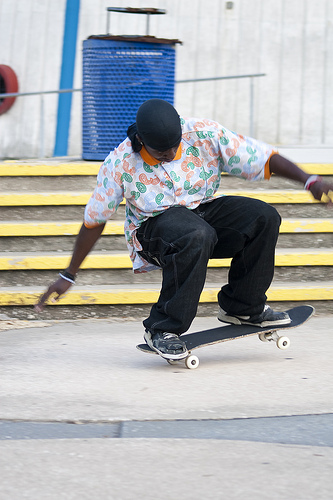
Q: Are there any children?
A: No, there are no children.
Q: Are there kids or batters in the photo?
A: No, there are no kids or batters.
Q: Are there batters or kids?
A: No, there are no kids or batters.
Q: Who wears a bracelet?
A: The guy wears a bracelet.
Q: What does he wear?
A: The guy wears a bracelet.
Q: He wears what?
A: The guy wears a bracelet.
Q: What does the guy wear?
A: The guy wears a bracelet.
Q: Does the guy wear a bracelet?
A: Yes, the guy wears a bracelet.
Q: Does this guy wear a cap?
A: No, the guy wears a bracelet.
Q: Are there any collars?
A: Yes, there is a collar.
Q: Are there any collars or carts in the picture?
A: Yes, there is a collar.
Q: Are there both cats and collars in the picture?
A: No, there is a collar but no cats.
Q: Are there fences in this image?
A: No, there are no fences.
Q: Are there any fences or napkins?
A: No, there are no fences or napkins.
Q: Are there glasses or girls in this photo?
A: No, there are no glasses or girls.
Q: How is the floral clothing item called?
A: The clothing item is a shirt.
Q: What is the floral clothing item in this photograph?
A: The clothing item is a shirt.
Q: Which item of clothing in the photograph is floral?
A: The clothing item is a shirt.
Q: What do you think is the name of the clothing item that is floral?
A: The clothing item is a shirt.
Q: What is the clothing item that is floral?
A: The clothing item is a shirt.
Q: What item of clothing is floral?
A: The clothing item is a shirt.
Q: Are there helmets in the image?
A: No, there are no helmets.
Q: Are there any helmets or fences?
A: No, there are no helmets or fences.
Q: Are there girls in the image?
A: No, there are no girls.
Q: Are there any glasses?
A: No, there are no glasses.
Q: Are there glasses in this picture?
A: No, there are no glasses.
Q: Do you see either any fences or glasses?
A: No, there are no glasses or fences.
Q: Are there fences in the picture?
A: No, there are no fences.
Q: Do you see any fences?
A: No, there are no fences.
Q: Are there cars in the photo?
A: No, there are no cars.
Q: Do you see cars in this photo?
A: No, there are no cars.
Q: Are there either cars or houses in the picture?
A: No, there are no cars or houses.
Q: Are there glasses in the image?
A: No, there are no glasses.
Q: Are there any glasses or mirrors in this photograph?
A: No, there are no glasses or mirrors.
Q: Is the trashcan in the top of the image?
A: Yes, the trashcan is in the top of the image.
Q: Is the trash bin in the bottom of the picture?
A: No, the trash bin is in the top of the image.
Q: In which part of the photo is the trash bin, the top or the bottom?
A: The trash bin is in the top of the image.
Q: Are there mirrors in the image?
A: No, there are no mirrors.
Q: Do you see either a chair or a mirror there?
A: No, there are no mirrors or chairs.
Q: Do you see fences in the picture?
A: No, there are no fences.